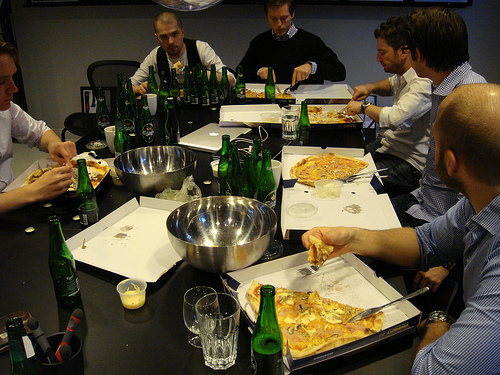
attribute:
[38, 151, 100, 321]
glass bottles — green 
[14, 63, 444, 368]
table — black 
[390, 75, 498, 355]
shirts — blue 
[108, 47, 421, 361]
table — black 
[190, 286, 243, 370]
glass — Colorless 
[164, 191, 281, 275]
bowl — silver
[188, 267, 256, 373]
glass — Green 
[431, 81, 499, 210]
head — balded 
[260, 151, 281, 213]
bottle — green 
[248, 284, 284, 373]
bottle — green 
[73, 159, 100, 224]
bottle — green 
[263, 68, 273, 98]
bottle — green 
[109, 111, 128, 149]
bottle — green 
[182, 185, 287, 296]
bowl — large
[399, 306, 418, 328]
box — cardboard